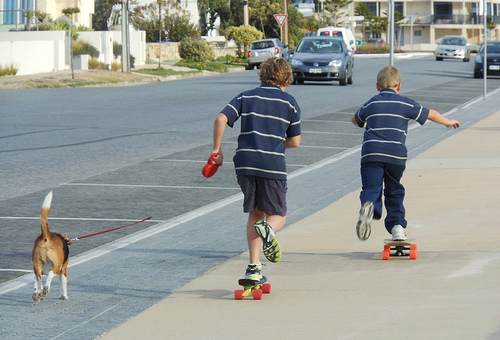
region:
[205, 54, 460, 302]
Two boys skateboarding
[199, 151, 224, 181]
Handle of the dog's leash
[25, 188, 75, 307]
Dog running alongside the boys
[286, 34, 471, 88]
Cars driving towards the boys direction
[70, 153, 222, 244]
Leash connecting to the dog's collar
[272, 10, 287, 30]
White and red triangular shaped street sign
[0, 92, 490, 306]
White lines running doen the side of the street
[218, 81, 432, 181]
The boy's matching shirts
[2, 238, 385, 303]
The shadows of the boys and dog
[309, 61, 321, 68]
Logo of the car's maker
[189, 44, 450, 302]
the are two boys skateboarding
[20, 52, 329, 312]
the boy is holding a leash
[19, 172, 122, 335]
the dog is brown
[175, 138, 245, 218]
the leash is red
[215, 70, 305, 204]
the shirt is stripes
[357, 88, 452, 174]
the shirt is blue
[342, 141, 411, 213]
the pants is blue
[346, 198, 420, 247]
the shoes is white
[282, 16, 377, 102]
the car is silver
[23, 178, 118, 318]
dog is on the leash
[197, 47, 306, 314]
boy on skateboard on sidewalk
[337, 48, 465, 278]
boy riding skateboard on the sidewalk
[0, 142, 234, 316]
dog on leash running down side of street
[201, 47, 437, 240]
two boys wearing navy blue shirts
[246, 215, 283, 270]
tennis shoe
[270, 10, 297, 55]
yield sign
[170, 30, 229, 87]
bush on sidewalk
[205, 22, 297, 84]
silver car parked along curb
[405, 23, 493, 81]
silver car travelling down street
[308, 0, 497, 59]
building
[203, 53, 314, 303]
brown haired boy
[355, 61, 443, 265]
blonde haired boy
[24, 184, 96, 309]
medium sized dog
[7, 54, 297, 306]
boy holding dog leash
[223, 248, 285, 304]
black skateboard with red wheels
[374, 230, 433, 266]
wooden skateboard with red wheels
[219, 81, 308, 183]
blue shirt with white stripes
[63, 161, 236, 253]
white lines on paved roads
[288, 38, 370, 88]
grey car on road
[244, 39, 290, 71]
silver car parked beside road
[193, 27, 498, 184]
There are two boys riding skate boards.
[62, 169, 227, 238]
One boy is holding a red leash.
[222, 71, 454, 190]
Both boys have blue and white striped shirts.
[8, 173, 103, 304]
The dog is black, tan and white.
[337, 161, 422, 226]
One boy is wearing blue pants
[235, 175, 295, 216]
One boy is wearing blue shorts.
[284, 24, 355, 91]
One car is driving the opposite direction of the boys.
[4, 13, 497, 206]
Picture is taken during the daytime.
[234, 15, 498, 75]
There are 5 vehicles in the picture.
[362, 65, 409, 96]
One boy's hair is blonde.